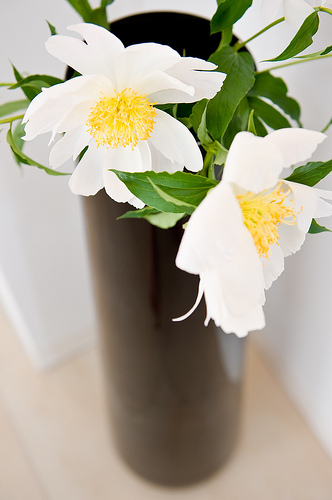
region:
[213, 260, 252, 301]
White petals on a flower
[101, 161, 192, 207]
Green pointed leaves on a flower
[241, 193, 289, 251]
Bright yellow stamens on a flower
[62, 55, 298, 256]
Two white flowers with yellow centers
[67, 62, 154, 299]
White flower in black vase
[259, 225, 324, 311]
Blank white wall behind flower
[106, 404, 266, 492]
Blurry black vase on beige countertop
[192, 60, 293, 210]
White flower surrounded by green leaves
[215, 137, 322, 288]
White flower with yellow center facing right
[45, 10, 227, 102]
White flower petals spreading outward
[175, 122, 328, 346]
a lovely white flower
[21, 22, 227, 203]
a lovely white flower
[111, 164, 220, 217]
a green tree leaf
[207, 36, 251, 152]
a green tree leaf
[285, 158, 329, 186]
a green tree leaf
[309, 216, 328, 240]
a green tree leaf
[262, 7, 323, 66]
a green tree leaf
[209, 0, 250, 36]
a green tree leaf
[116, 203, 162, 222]
a green tree leaf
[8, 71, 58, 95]
a green tree leaf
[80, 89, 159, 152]
Middle yellow part of a flower.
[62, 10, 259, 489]
A dark brown vase holding 2 flowers.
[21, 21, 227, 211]
Large white and orange flower to the left of another flower.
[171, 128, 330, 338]
White and orange flower to the right of another larger flower.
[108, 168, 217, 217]
Green leaf in between two flowers.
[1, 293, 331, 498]
Light wood floor under the vase.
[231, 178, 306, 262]
Orange middle of a flower on the right.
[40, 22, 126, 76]
Top two petals on the top left.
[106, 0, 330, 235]
All the leaves on the right side of the vase.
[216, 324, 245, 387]
Oval shaped reflection on the right side of the vase.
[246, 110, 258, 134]
a green tree leaf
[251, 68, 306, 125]
a green tree leaf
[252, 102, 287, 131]
a green tree leaf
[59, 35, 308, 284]
the flowers are white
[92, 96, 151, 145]
the flower center is yellow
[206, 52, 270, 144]
the leaves are green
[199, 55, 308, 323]
leaves are behind flowers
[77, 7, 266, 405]
the flowers in vase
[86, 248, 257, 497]
the vase is brown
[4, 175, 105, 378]
the walls are white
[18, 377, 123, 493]
the floor is tan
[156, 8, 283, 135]
the leaves are in vase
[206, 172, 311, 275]
the flower has petals